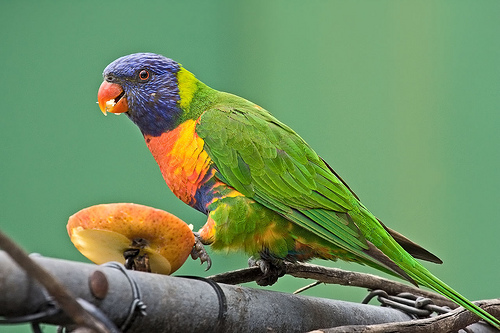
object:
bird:
[94, 52, 500, 333]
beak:
[94, 81, 129, 116]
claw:
[179, 232, 212, 272]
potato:
[66, 203, 194, 276]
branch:
[0, 253, 498, 333]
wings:
[198, 105, 421, 289]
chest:
[144, 130, 218, 210]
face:
[97, 52, 180, 129]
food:
[105, 98, 116, 109]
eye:
[135, 68, 152, 83]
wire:
[97, 261, 150, 332]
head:
[96, 52, 199, 130]